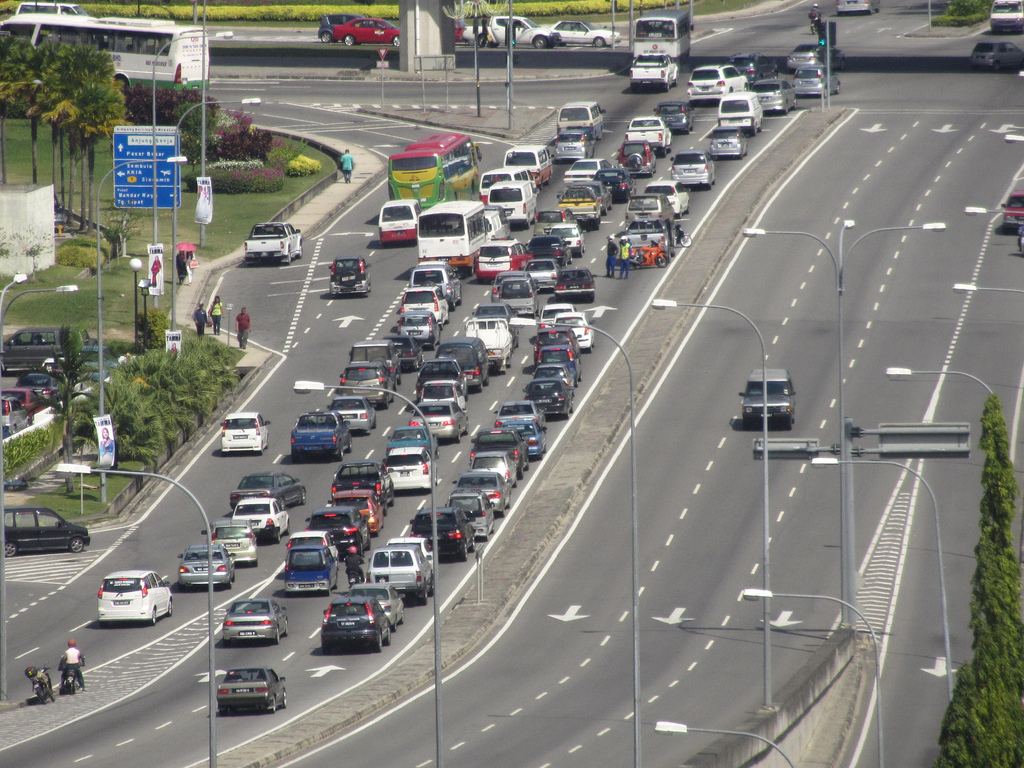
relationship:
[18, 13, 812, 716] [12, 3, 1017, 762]
traffic on side road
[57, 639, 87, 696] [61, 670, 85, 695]
man on motorcycle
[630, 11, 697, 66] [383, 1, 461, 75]
bus under bridge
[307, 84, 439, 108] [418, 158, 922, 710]
arrow on street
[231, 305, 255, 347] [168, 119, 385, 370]
person walking on sidewalk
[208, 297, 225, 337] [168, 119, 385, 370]
person walking on sidewalk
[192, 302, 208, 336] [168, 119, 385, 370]
person walking on sidewalk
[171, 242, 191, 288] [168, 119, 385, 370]
person walking on sidewalk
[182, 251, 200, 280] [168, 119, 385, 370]
person walking on sidewalk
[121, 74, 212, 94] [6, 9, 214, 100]
bottom belonging to bus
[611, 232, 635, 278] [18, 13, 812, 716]
man diverting traffic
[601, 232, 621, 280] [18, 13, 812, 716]
man diverting traffic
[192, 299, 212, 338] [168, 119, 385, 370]
person walking on sidewalk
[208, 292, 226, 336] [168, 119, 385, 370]
person walking on sidewalk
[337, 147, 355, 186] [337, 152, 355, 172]
guy wearing shirt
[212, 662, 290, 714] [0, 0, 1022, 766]
car driving on road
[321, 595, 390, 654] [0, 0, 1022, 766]
car driving on road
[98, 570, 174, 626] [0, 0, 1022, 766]
car driving on road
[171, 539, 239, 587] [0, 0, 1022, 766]
car driving on road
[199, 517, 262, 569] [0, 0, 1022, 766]
car driving on road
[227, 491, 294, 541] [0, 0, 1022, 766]
car driving on road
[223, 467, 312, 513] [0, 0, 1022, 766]
car driving on road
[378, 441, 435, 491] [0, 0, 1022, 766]
car driving on road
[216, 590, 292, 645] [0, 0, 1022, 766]
car driving on road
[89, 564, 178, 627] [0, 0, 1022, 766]
car driving on road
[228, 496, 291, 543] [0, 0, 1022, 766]
car driving on road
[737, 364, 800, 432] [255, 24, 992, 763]
car driving on street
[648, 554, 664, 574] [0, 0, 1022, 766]
line painted on road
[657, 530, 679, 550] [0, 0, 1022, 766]
line painted on road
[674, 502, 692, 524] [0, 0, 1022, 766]
line painted on road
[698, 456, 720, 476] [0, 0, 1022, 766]
line painted on road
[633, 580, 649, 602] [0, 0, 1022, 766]
line painted on road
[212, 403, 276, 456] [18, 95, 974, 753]
car on street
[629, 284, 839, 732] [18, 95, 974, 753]
pole next to street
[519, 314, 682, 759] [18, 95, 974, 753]
pole next to street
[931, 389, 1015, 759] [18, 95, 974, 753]
tree next to street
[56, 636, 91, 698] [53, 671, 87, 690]
man on motorcycle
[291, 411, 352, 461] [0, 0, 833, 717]
truck in traffic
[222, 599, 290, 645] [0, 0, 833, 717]
car in traffic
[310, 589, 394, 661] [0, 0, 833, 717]
car in traffic